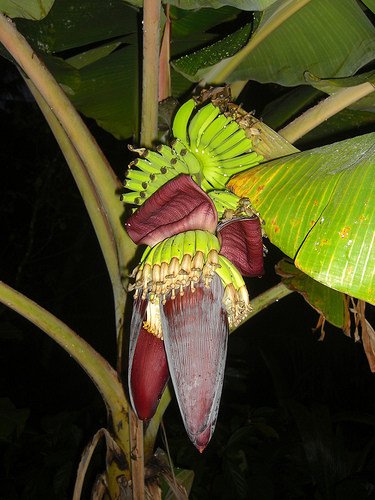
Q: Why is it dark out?
A: It is night time.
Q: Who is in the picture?
A: No one is in the picture.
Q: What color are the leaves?
A: Green.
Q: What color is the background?
A: Black.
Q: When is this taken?
A: At night.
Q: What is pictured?
A: A plant.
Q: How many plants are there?
A: One.